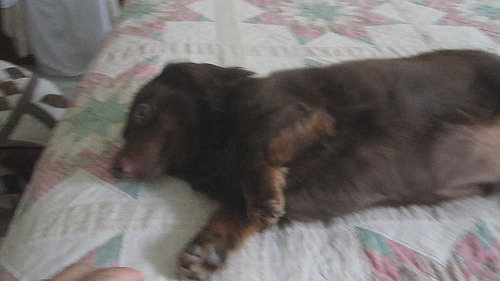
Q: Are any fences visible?
A: No, there are no fences.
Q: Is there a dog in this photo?
A: Yes, there is a dog.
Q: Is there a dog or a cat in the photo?
A: Yes, there is a dog.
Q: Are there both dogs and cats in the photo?
A: No, there is a dog but no cats.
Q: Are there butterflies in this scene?
A: No, there are no butterflies.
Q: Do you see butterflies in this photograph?
A: No, there are no butterflies.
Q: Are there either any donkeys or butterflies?
A: No, there are no butterflies or donkeys.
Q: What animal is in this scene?
A: The animal is a dog.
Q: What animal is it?
A: The animal is a dog.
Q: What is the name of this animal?
A: This is a dog.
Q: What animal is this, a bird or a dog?
A: This is a dog.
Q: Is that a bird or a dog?
A: That is a dog.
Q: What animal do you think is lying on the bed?
A: The dog is lying on the bed.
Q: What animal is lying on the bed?
A: The dog is lying on the bed.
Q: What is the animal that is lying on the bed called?
A: The animal is a dog.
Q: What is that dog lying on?
A: The dog is lying on the bed.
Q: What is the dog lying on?
A: The dog is lying on the bed.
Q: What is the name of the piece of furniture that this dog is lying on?
A: The piece of furniture is a bed.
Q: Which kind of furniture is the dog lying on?
A: The dog is lying on the bed.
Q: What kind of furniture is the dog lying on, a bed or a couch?
A: The dog is lying on a bed.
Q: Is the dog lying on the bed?
A: Yes, the dog is lying on the bed.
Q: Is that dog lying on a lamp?
A: No, the dog is lying on the bed.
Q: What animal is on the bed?
A: The dog is on the bed.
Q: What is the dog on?
A: The dog is on the bed.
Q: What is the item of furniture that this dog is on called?
A: The piece of furniture is a bed.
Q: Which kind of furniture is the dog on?
A: The dog is on the bed.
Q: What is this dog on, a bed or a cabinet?
A: The dog is on a bed.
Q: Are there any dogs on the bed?
A: Yes, there is a dog on the bed.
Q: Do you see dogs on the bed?
A: Yes, there is a dog on the bed.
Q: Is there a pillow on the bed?
A: No, there is a dog on the bed.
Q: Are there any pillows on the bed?
A: No, there is a dog on the bed.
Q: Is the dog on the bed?
A: Yes, the dog is on the bed.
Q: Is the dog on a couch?
A: No, the dog is on the bed.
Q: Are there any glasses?
A: No, there are no glasses.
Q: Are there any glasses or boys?
A: No, there are no glasses or boys.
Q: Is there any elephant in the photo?
A: No, there are no elephants.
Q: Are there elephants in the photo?
A: No, there are no elephants.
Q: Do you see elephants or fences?
A: No, there are no elephants or fences.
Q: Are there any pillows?
A: No, there are no pillows.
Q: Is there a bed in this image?
A: Yes, there is a bed.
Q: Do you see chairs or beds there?
A: Yes, there is a bed.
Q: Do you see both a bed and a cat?
A: No, there is a bed but no cats.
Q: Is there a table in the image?
A: No, there are no tables.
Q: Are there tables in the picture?
A: No, there are no tables.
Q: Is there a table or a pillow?
A: No, there are no tables or pillows.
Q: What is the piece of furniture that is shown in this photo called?
A: The piece of furniture is a bed.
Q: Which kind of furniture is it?
A: The piece of furniture is a bed.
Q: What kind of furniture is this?
A: This is a bed.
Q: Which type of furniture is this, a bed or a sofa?
A: This is a bed.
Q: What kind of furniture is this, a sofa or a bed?
A: This is a bed.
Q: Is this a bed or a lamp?
A: This is a bed.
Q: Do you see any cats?
A: No, there are no cats.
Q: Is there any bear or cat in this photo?
A: No, there are no cats or bears.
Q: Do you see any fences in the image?
A: No, there are no fences.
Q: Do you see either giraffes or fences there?
A: No, there are no fences or giraffes.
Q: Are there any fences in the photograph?
A: No, there are no fences.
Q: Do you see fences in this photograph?
A: No, there are no fences.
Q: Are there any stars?
A: Yes, there is a star.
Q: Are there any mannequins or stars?
A: Yes, there is a star.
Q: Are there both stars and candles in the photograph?
A: No, there is a star but no candles.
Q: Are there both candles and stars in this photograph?
A: No, there is a star but no candles.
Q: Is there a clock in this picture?
A: No, there are no clocks.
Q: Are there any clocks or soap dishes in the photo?
A: No, there are no clocks or soap dishes.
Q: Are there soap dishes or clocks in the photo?
A: No, there are no clocks or soap dishes.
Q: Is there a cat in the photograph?
A: No, there are no cats.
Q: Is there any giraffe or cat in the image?
A: No, there are no cats or giraffes.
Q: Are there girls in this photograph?
A: No, there are no girls.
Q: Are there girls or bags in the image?
A: No, there are no girls or bags.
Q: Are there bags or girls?
A: No, there are no girls or bags.